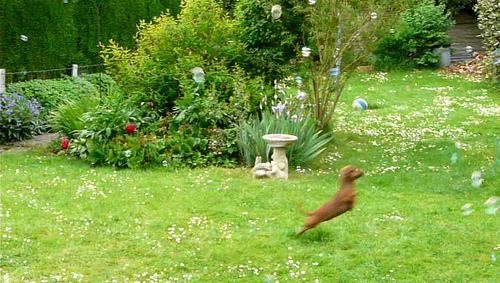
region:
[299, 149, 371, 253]
A small brown dog.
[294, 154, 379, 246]
A dog jumping in the air.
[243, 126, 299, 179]
A concrete bird bath.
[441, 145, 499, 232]
Bubbles in the air.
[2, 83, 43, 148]
A bush with purple flowers.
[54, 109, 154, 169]
Two red flowers.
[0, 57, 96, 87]
Two fence posts.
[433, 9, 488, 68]
Set of steps in the background.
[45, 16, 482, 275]
Dog playing in a yard.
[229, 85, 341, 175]
A section of iris flowers.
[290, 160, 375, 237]
the dog is brown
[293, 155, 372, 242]
the dog is jumping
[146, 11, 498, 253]
bubbles are floating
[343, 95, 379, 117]
the ball is blue and white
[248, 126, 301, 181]
a bird bath by the tree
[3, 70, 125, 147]
a row of bushes on the left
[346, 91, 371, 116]
the ball is in the grass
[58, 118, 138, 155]
the flowers are red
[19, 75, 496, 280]
the grass has patches of white flowers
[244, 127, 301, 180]
the bird bath is tan colored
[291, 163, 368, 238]
a dog leaping in the air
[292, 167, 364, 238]
a brown dog leaping in the air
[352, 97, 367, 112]
a ball laying in the grass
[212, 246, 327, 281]
white flowers in the grass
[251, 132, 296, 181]
a birdbath by the plants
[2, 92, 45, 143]
lilacs on the left of garde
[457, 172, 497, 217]
soap bubbles in the air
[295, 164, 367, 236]
dog chasing soap bubbles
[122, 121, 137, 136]
a large red blossom in the garden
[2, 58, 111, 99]
a fence beyond the garden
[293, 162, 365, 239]
a small brown dog jumping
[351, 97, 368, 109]
a blue and white ball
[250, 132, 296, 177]
a decorative bird feeder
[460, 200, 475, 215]
a clear floating bubble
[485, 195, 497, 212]
a clear floating bubble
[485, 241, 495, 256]
a clear floating bubble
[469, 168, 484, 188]
a clear floating bubble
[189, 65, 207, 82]
a clear floating bubble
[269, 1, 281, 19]
a clear floating bubble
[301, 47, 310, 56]
a clear floating bubble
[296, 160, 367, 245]
Brown puppy jumping in air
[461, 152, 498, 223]
Bubbles bubbling in air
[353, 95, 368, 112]
White and blue ball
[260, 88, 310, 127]
White flowers on plant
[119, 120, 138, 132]
Red flower on leaves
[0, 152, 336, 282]
White flowers on grass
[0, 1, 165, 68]
Green fence in the background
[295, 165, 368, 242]
Puppy playing in field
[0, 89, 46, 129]
Purple flowers on plant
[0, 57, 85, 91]
White poles of a fence